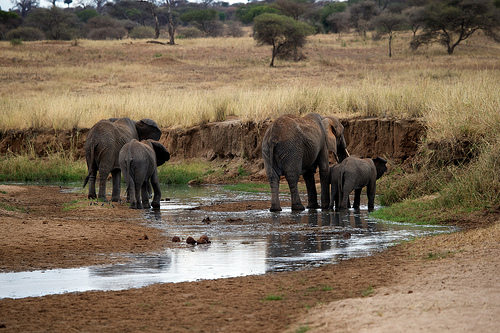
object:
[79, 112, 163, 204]
elephants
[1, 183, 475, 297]
water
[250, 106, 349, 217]
elephant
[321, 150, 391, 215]
elephant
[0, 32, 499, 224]
grass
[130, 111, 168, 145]
large ears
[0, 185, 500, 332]
river bank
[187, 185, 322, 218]
island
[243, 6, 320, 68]
bushes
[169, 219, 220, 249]
rocks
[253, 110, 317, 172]
rears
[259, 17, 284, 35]
green leaves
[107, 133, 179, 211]
elephant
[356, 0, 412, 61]
trees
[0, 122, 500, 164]
ledge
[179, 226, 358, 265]
reflection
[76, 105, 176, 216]
pairs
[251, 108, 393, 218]
pair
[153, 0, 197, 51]
tree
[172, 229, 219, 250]
feces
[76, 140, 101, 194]
tail